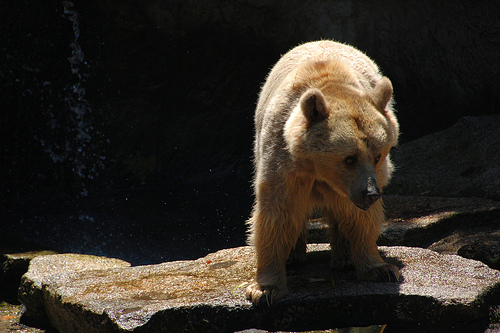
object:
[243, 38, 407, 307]
bear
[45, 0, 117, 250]
water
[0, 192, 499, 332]
pool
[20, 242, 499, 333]
rock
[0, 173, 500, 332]
ground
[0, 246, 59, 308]
rock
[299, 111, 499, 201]
rock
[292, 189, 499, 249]
rock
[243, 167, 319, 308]
leg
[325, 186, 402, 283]
leg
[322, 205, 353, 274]
leg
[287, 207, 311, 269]
leg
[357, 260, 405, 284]
front paw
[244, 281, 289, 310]
front paw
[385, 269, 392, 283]
claw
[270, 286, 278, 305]
claw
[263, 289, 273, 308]
claw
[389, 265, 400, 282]
claw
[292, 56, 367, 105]
ruff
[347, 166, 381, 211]
snout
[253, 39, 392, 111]
back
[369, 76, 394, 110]
ear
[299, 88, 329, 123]
ear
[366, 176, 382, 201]
nose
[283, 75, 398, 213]
head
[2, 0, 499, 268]
background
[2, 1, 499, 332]
enclosure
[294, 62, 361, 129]
fur